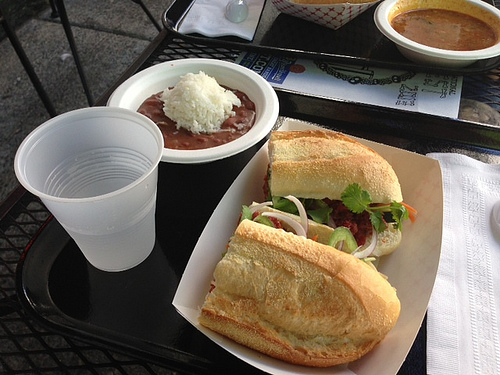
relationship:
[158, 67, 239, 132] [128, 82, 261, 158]
rice on beans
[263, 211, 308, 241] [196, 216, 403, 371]
onion in bread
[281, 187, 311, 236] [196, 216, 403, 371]
onion in bread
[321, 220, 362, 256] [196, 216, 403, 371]
pepper in bread